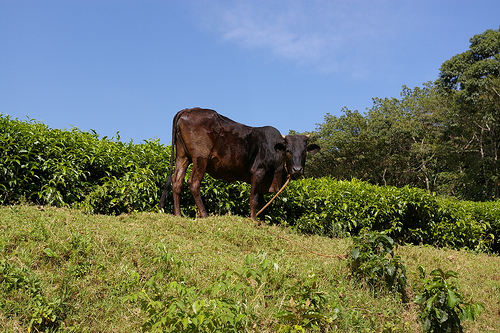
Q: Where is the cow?
A: In the pasture.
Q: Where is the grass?
A: On the ground.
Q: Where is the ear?
A: On the cow.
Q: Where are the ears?
A: On the cow.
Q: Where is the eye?
A: On the cat.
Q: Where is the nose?
A: On the cow.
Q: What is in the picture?
A: An animal.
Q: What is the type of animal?
A: Cow.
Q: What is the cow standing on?
A: Grass.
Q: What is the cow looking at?
A: The camera.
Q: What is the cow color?
A: Dark brown.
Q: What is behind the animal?
A: Lots of tree.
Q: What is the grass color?
A: Green and tan.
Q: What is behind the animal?
A: Bushes.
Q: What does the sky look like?
A: Clear and blue.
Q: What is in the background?
A: Green foliage.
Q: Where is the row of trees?
A: By field.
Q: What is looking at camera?
A: A cow.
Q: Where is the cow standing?
A: On grass.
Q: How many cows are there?
A: One.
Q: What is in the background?
A: A meadow.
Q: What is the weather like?
A: Sunny.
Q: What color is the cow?
A: Brown.